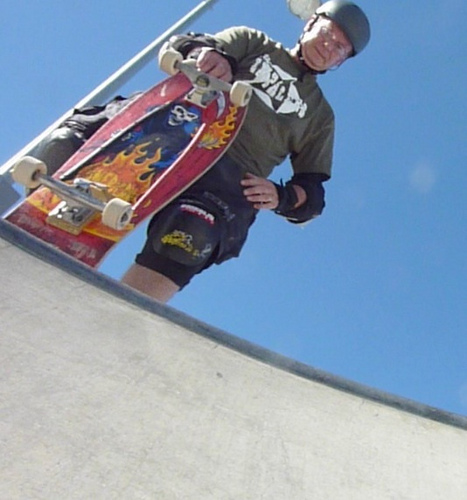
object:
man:
[21, 0, 370, 309]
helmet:
[313, 0, 370, 56]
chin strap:
[294, 41, 326, 74]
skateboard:
[6, 39, 257, 272]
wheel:
[229, 80, 253, 113]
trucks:
[48, 178, 112, 231]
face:
[166, 102, 200, 127]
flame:
[23, 139, 166, 237]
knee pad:
[148, 198, 226, 277]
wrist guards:
[269, 177, 297, 223]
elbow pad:
[290, 175, 327, 229]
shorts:
[141, 158, 263, 266]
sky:
[0, 0, 466, 430]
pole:
[0, 0, 210, 181]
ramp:
[0, 229, 463, 498]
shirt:
[207, 21, 335, 198]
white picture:
[246, 52, 310, 121]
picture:
[159, 229, 193, 252]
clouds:
[399, 159, 438, 204]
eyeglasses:
[312, 22, 348, 56]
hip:
[211, 154, 273, 226]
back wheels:
[101, 196, 133, 232]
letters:
[178, 201, 216, 226]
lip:
[313, 41, 326, 67]